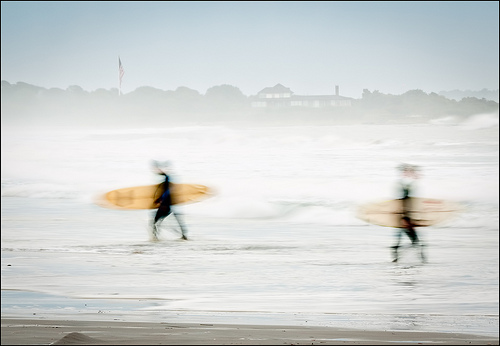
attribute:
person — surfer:
[149, 155, 189, 243]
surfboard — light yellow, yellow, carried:
[99, 178, 214, 212]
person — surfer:
[389, 179, 430, 268]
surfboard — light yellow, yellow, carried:
[349, 193, 457, 230]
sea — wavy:
[9, 113, 500, 332]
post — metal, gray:
[116, 56, 122, 104]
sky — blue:
[1, 0, 497, 97]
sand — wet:
[1, 309, 499, 344]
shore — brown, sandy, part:
[2, 278, 499, 344]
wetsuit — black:
[150, 172, 186, 232]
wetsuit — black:
[395, 188, 423, 250]